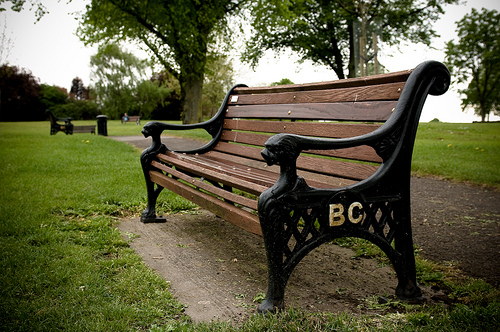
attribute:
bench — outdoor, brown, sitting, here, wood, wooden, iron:
[164, 87, 408, 242]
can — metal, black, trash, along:
[83, 102, 125, 142]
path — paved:
[449, 194, 492, 241]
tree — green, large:
[459, 18, 487, 78]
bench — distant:
[56, 109, 109, 138]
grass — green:
[25, 190, 125, 284]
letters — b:
[315, 193, 351, 223]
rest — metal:
[249, 120, 467, 153]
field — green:
[6, 149, 93, 297]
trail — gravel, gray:
[412, 177, 490, 251]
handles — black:
[252, 128, 367, 161]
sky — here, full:
[39, 19, 97, 68]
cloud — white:
[39, 18, 69, 53]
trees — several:
[88, 14, 442, 76]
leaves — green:
[103, 16, 138, 52]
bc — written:
[297, 194, 375, 230]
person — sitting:
[114, 102, 149, 132]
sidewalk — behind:
[122, 117, 240, 165]